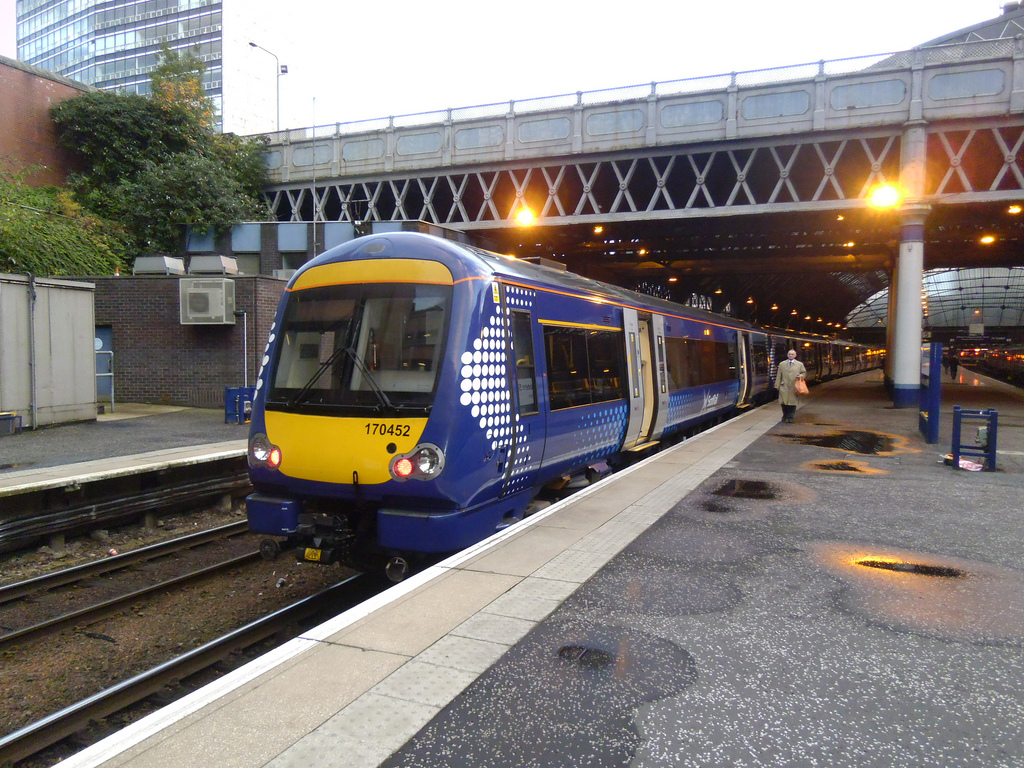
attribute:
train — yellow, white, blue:
[209, 266, 704, 465]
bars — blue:
[915, 407, 993, 470]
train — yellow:
[248, 247, 463, 505]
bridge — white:
[293, 44, 991, 228]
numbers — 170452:
[365, 420, 415, 442]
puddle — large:
[816, 426, 896, 483]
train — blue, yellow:
[257, 219, 683, 516]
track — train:
[19, 579, 233, 690]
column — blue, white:
[881, 199, 936, 418]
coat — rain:
[779, 364, 792, 393]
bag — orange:
[797, 381, 817, 412]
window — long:
[517, 314, 632, 421]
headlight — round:
[379, 433, 438, 496]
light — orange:
[487, 184, 594, 288]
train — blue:
[230, 199, 922, 582]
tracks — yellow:
[29, 517, 345, 675]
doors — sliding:
[11, 273, 128, 442]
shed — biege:
[9, 210, 141, 472]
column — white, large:
[880, 189, 948, 427]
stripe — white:
[178, 372, 770, 755]